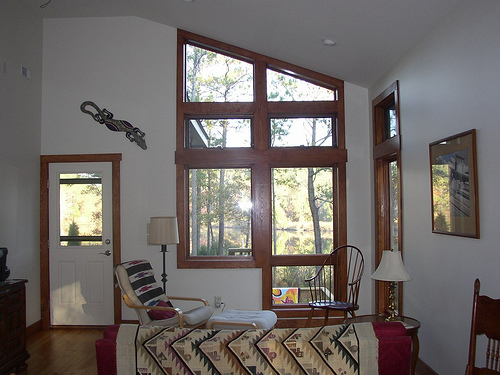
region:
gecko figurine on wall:
[67, 97, 154, 153]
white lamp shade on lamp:
[379, 236, 414, 293]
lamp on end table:
[378, 240, 412, 322]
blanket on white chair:
[118, 265, 178, 316]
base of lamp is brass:
[377, 277, 407, 322]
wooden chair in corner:
[312, 237, 362, 317]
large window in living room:
[181, 87, 346, 303]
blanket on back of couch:
[135, 327, 376, 368]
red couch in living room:
[100, 325, 417, 370]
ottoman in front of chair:
[211, 312, 283, 330]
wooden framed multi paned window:
[150, 28, 361, 323]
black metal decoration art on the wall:
[69, 94, 153, 155]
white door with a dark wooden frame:
[35, 148, 124, 328]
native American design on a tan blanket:
[115, 314, 389, 371]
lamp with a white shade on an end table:
[362, 244, 425, 366]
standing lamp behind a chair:
[145, 213, 176, 305]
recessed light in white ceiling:
[315, 28, 339, 55]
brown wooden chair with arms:
[300, 240, 367, 325]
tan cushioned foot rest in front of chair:
[202, 301, 287, 333]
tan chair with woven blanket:
[107, 253, 211, 333]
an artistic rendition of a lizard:
[78, 98, 148, 150]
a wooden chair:
[302, 243, 364, 326]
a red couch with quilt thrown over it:
[92, 323, 413, 374]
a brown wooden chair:
[464, 275, 499, 373]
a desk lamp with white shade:
[367, 246, 412, 323]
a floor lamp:
[145, 214, 181, 296]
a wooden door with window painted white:
[47, 160, 117, 326]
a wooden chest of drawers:
[0, 278, 32, 374]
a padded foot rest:
[206, 307, 278, 329]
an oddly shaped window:
[174, 28, 347, 320]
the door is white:
[39, 147, 123, 325]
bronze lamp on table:
[334, 249, 421, 373]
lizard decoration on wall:
[76, 97, 146, 153]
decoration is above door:
[37, 96, 148, 327]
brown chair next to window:
[262, 244, 367, 327]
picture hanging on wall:
[424, 125, 481, 240]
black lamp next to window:
[146, 212, 182, 323]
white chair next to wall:
[113, 257, 281, 335]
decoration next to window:
[77, 99, 150, 154]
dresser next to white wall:
[1, 245, 31, 373]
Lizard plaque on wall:
[78, 97, 152, 152]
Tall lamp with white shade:
[144, 212, 184, 299]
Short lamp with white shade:
[368, 244, 416, 324]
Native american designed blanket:
[109, 317, 384, 374]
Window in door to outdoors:
[56, 169, 106, 249]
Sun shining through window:
[234, 194, 252, 214]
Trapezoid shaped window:
[181, 37, 258, 105]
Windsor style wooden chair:
[302, 239, 369, 326]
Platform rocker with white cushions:
[109, 257, 214, 327]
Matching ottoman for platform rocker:
[205, 302, 279, 330]